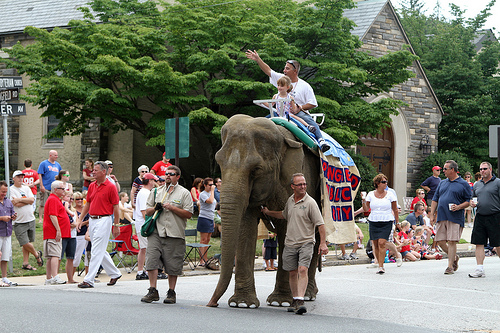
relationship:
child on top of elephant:
[260, 74, 316, 134] [205, 113, 359, 307]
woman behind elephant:
[360, 171, 400, 275] [205, 113, 359, 307]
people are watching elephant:
[1, 152, 499, 282] [205, 113, 359, 307]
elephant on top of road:
[205, 113, 359, 307] [0, 244, 500, 332]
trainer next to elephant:
[141, 165, 195, 305] [205, 113, 359, 307]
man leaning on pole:
[9, 169, 47, 271] [2, 119, 15, 200]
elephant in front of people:
[205, 113, 359, 307] [357, 159, 499, 280]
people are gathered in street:
[1, 152, 499, 282] [0, 244, 500, 332]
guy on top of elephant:
[244, 50, 331, 153] [205, 113, 359, 307]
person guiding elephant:
[260, 172, 329, 313] [205, 113, 359, 307]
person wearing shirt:
[260, 172, 329, 313] [281, 191, 323, 243]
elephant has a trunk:
[205, 113, 359, 307] [205, 169, 253, 308]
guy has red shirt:
[76, 160, 124, 289] [86, 178, 119, 212]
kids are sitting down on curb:
[372, 220, 447, 261] [0, 246, 500, 283]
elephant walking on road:
[205, 113, 359, 307] [0, 244, 500, 332]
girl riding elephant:
[260, 74, 316, 134] [205, 113, 359, 307]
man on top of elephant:
[244, 50, 331, 153] [205, 113, 359, 307]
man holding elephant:
[260, 172, 329, 313] [205, 113, 359, 307]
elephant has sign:
[205, 113, 359, 307] [317, 133, 363, 244]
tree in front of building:
[4, 2, 417, 211] [5, 0, 446, 214]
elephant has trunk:
[205, 113, 359, 307] [205, 169, 253, 308]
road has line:
[0, 244, 500, 332] [183, 270, 499, 321]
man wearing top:
[134, 171, 155, 280] [135, 188, 152, 235]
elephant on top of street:
[205, 113, 359, 307] [0, 244, 500, 332]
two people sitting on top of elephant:
[244, 48, 332, 151] [205, 113, 359, 307]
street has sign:
[0, 244, 500, 332] [0, 73, 29, 200]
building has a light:
[5, 0, 446, 214] [419, 131, 433, 156]